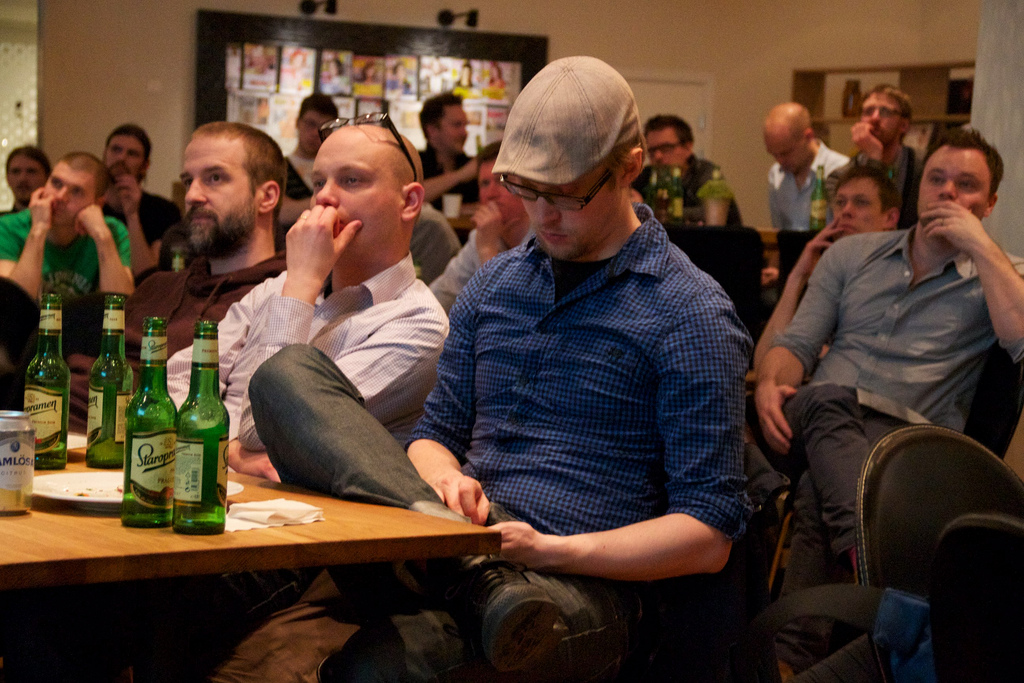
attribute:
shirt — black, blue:
[425, 202, 757, 573]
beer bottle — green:
[171, 317, 235, 520]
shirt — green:
[1, 201, 142, 310]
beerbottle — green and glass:
[163, 305, 255, 537]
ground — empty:
[859, 354, 916, 408]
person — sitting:
[42, 117, 284, 424]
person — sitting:
[240, 114, 436, 390]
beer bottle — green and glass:
[175, 279, 249, 532]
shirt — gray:
[782, 223, 992, 433]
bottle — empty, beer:
[172, 308, 224, 536]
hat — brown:
[495, 80, 626, 163]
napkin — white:
[227, 482, 329, 539]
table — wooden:
[0, 466, 504, 604]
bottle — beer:
[153, 310, 236, 537]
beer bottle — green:
[182, 426, 224, 651]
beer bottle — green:
[171, 319, 221, 637]